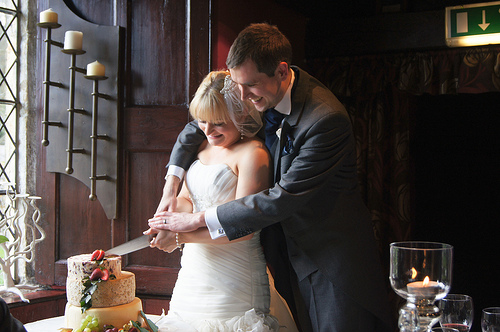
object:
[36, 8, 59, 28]
candles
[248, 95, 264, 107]
man`s mouth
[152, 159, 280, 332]
dress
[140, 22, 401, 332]
couple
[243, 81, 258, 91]
eyes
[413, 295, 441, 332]
candle holder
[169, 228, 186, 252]
bracelet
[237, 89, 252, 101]
nose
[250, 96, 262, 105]
lips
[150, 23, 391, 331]
man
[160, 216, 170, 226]
ring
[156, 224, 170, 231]
finger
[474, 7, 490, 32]
arrow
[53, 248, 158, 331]
cake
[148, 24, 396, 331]
groom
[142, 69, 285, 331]
bride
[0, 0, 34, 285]
window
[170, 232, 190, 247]
wrist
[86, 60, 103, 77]
candle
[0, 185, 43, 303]
tree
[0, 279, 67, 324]
window sill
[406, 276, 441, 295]
candle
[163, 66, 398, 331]
coat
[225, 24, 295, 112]
head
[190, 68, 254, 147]
head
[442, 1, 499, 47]
sign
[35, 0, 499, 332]
wall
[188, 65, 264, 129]
hair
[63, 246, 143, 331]
wedding cake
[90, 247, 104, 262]
flowers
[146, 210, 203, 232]
hand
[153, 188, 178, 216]
hand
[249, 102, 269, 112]
chin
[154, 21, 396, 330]
man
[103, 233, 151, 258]
knife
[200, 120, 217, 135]
nose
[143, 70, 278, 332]
woman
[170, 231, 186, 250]
pearls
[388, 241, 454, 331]
glass